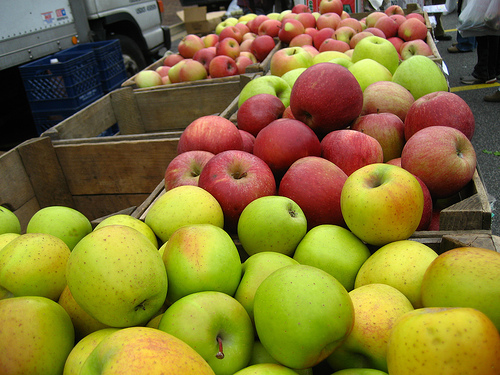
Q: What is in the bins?
A: Apples.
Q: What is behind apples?
A: Stack of blue bins.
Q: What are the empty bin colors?
A: Light brown wood.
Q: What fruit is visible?
A: Apples.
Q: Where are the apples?
A: In baskets.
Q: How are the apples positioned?
A: In piles.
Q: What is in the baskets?
A: Apples.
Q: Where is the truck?
A: On the left of the apples.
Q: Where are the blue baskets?
A: To the right of the truck.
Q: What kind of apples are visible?
A: Red and green apples.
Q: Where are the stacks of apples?
A: On the street.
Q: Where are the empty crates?
A: On the left side of the pile of apples.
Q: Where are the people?
A: In the right corner.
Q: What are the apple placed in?
A: Crates.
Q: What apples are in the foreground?
A: Yellow.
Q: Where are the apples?
A: At the market.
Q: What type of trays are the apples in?
A: Wooden.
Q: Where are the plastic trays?
A: Next to the wooden trays.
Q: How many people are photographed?
A: Two.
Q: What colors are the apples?
A: Yellow and red.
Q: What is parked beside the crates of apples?
A: A truck.